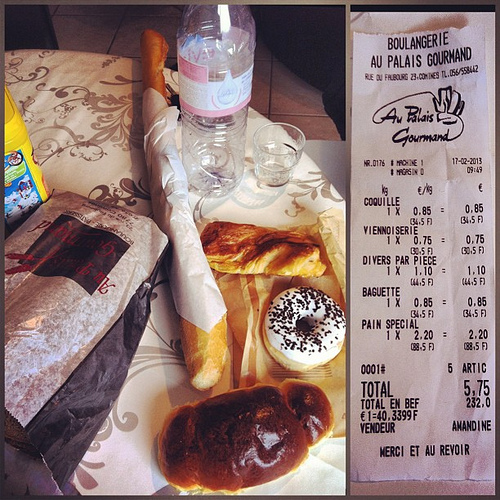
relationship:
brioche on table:
[157, 387, 326, 477] [6, 25, 399, 497]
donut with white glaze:
[262, 284, 347, 373] [267, 327, 283, 350]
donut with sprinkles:
[262, 284, 347, 373] [298, 283, 328, 306]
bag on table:
[4, 187, 169, 427] [3, 47, 348, 498]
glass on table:
[246, 111, 309, 194] [3, 47, 348, 498]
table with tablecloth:
[3, 47, 348, 498] [31, 72, 123, 165]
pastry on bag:
[178, 184, 370, 376] [191, 228, 352, 435]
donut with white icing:
[264, 284, 347, 369] [264, 288, 343, 360]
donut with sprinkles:
[262, 284, 347, 373] [269, 288, 339, 353]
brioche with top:
[157, 377, 335, 495] [178, 410, 300, 465]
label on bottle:
[169, 48, 265, 122] [175, 0, 255, 197]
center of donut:
[293, 311, 316, 338] [259, 286, 346, 371]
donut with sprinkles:
[262, 284, 347, 373] [275, 291, 303, 312]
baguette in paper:
[138, 24, 230, 389] [141, 86, 229, 333]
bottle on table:
[175, 4, 255, 197] [3, 47, 348, 498]